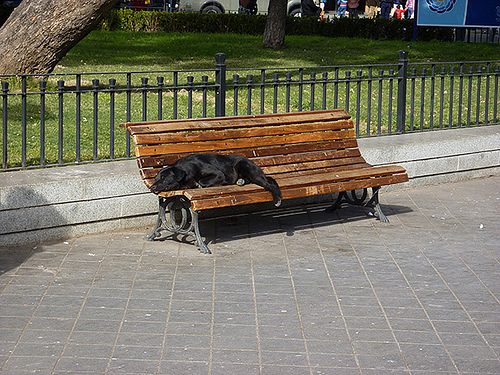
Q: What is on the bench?
A: Dog.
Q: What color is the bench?
A: Brown.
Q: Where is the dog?
A: On a bench.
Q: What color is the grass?
A: Green.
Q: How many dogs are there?
A: One.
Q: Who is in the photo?
A: A dog.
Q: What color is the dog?
A: Black.